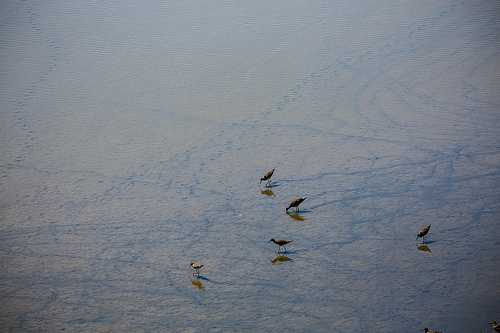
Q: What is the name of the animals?
A: Birds.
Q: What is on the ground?
A: Water.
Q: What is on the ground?
A: Birds.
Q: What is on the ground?
A: Water.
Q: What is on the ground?
A: Birds.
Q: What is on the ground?
A: Ice.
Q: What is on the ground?
A: Ice.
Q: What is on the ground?
A: Birds.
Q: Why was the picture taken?
A: To capture birds activities.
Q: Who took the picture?
A: Bird watcher.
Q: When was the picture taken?
A: Almost night.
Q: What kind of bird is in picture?
A: Sandpiper.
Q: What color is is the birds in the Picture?
A: Brownish gray.